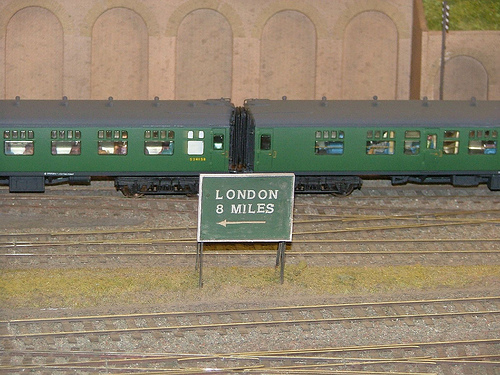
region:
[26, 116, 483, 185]
the train is green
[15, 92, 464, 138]
train's roof is gray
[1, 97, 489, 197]
Green and grey model train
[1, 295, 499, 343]
Tracks for model train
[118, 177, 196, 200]
Wheels on small train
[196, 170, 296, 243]
"London 8 Miles" sign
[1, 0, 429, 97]
Miniature brick wall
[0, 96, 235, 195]
Green model train car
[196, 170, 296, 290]
Sign pointing towards London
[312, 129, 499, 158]
Windows on miniature train car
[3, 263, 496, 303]
Pretend grass for miniature set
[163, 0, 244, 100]
Red brick arch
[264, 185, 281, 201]
white letter on a green sign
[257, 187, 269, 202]
white letter on a green sign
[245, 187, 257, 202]
white letter on a green sign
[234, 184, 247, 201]
white letter on a green sign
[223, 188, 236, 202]
white letter on a green sign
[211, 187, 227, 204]
white letter on a green sign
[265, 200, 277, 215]
white letter on a green sign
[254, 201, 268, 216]
white letter on a green sign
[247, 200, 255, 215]
white letter on a green sign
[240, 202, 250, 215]
white letter on a green sign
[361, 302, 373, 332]
cross tie on the track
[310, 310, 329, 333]
cross tie on the track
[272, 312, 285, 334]
cross tie on the track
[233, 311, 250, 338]
cross tie on the track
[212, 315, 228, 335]
cross tie on the track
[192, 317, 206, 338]
cross tie on the track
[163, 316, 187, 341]
cross tie on the track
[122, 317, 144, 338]
cross tie on the track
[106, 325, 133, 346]
cross tie on the track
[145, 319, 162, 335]
cross tie on the track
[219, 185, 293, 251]
Gree direction sign in the ground.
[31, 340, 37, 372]
Gree direction sign in the ground.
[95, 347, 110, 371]
Gree direction sign in the ground.